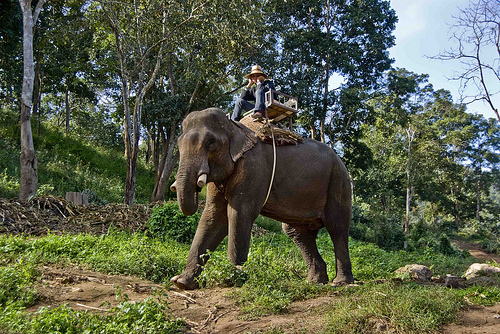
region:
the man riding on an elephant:
[175, 63, 362, 294]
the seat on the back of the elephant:
[258, 86, 298, 135]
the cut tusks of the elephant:
[168, 173, 210, 193]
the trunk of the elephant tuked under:
[176, 176, 201, 220]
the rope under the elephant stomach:
[259, 120, 281, 212]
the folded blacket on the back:
[241, 115, 301, 152]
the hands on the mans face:
[241, 72, 269, 97]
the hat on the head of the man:
[238, 59, 269, 79]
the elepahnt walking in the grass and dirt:
[148, 108, 361, 293]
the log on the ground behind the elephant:
[388, 250, 496, 302]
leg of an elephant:
[167, 215, 214, 289]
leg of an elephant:
[208, 241, 253, 296]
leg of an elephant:
[288, 239, 323, 277]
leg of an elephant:
[325, 245, 352, 280]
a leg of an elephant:
[165, 233, 213, 293]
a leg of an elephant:
[217, 215, 264, 317]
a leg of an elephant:
[281, 241, 323, 305]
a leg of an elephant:
[327, 246, 354, 281]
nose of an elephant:
[171, 161, 209, 219]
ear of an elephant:
[222, 116, 246, 171]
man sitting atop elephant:
[226, 60, 278, 122]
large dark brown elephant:
[164, 103, 357, 292]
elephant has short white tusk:
[196, 173, 207, 188]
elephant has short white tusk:
[168, 175, 182, 198]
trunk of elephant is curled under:
[173, 156, 202, 218]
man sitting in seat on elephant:
[231, 85, 299, 125]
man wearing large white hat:
[244, 60, 268, 78]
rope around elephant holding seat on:
[258, 108, 278, 210]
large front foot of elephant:
[166, 268, 198, 289]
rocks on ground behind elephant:
[394, 257, 499, 286]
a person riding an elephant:
[231, 65, 298, 146]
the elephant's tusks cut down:
[171, 176, 205, 188]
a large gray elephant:
[170, 110, 351, 286]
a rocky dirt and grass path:
[21, 220, 498, 330]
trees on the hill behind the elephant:
[5, 1, 498, 227]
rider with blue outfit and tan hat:
[231, 65, 276, 122]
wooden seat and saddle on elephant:
[240, 93, 300, 145]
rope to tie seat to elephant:
[256, 118, 275, 213]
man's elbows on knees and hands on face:
[239, 77, 264, 94]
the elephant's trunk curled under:
[176, 161, 196, 215]